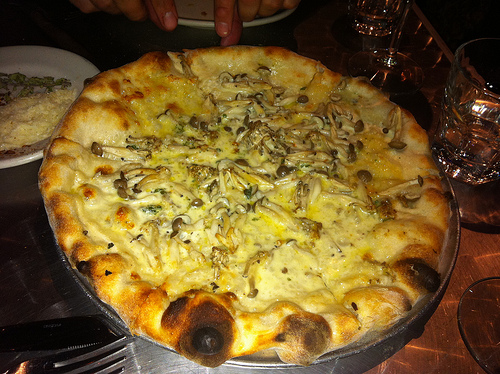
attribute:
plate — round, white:
[6, 38, 100, 179]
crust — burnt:
[157, 289, 238, 372]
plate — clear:
[455, 269, 498, 372]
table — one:
[10, 7, 497, 372]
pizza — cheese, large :
[41, 45, 453, 370]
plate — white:
[1, 38, 113, 187]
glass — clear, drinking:
[417, 33, 496, 144]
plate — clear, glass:
[440, 280, 493, 334]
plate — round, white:
[143, 0, 290, 40]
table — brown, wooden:
[387, 240, 498, 354]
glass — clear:
[418, 66, 493, 156]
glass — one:
[348, 2, 433, 92]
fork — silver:
[16, 325, 129, 373]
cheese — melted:
[140, 96, 347, 283]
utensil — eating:
[21, 336, 126, 373]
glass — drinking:
[440, 36, 498, 206]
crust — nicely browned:
[44, 46, 458, 366]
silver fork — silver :
[0, 332, 137, 371]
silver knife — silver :
[6, 314, 121, 357]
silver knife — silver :
[0, 316, 136, 357]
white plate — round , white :
[0, 43, 108, 169]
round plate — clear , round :
[455, 270, 498, 371]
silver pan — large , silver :
[30, 41, 473, 362]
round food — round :
[47, 35, 457, 362]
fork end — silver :
[0, 330, 133, 371]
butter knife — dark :
[0, 313, 117, 346]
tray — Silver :
[43, 46, 462, 371]